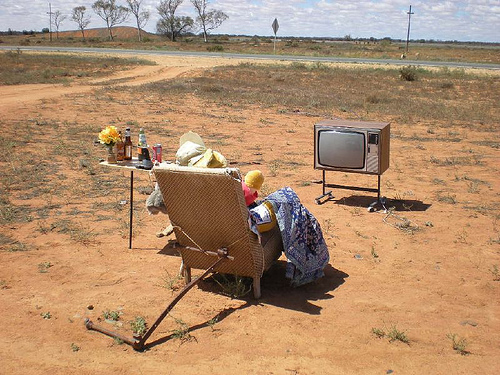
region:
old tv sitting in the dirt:
[303, 113, 393, 212]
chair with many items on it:
[156, 142, 329, 287]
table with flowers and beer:
[99, 122, 162, 172]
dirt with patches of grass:
[14, 56, 499, 371]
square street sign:
[269, 16, 280, 53]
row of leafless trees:
[42, 4, 227, 39]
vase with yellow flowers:
[96, 120, 119, 165]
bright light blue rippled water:
[8, 2, 488, 38]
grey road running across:
[4, 30, 498, 82]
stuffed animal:
[193, 142, 265, 212]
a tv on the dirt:
[287, 88, 424, 210]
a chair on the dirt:
[117, 162, 309, 335]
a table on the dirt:
[71, 82, 186, 250]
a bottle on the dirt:
[110, 130, 165, 185]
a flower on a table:
[89, 110, 147, 190]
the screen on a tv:
[304, 111, 379, 168]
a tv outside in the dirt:
[286, 101, 418, 208]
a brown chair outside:
[148, 125, 328, 287]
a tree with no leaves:
[136, 2, 202, 59]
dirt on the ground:
[314, 252, 433, 352]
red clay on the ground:
[353, 272, 418, 302]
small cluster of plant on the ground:
[366, 319, 407, 342]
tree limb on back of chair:
[82, 248, 232, 356]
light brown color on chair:
[174, 183, 237, 226]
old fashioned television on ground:
[301, 116, 414, 214]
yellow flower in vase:
[87, 114, 121, 151]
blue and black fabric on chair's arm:
[265, 187, 337, 288]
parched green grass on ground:
[248, 75, 336, 94]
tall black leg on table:
[119, 172, 146, 247]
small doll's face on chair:
[237, 161, 284, 203]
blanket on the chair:
[275, 191, 332, 296]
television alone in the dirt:
[301, 120, 414, 211]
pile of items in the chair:
[168, 154, 315, 264]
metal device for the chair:
[79, 238, 237, 350]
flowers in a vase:
[96, 121, 129, 184]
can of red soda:
[151, 139, 169, 168]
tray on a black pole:
[99, 166, 147, 253]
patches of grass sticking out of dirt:
[364, 327, 470, 371]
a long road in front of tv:
[10, 58, 499, 66]